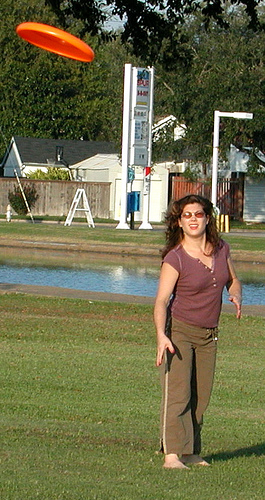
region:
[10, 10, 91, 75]
An orange Frisbee in the air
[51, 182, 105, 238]
A white signboard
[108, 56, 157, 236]
A large white sign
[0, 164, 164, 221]
A brown wooden fence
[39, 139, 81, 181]
A basketball net behind the house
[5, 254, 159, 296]
A stream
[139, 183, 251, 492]
The woman is ready to catch the Frisbee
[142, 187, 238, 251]
She is wearing sunglasses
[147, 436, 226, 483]
The woman is barefoot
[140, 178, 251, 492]
The woman is wearing brown pants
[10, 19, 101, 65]
orange plastic frisbee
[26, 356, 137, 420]
field covered in green grass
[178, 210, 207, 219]
orange tinted eye glasses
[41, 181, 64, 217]
brown wooden privacy fence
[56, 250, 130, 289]
small stream behind field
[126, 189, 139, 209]
blue cover of pay phone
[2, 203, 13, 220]
white fire hydrant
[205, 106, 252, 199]
white metal street light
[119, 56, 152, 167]
large metal company sign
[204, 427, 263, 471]
shadow of woman in field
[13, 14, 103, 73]
frisbee in the air.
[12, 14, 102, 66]
the frisbee is orange.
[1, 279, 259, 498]
the grass is green.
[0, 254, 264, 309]
the water is blue.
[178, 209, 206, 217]
woman is wearing sunglasses.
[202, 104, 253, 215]
the light post is white.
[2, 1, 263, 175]
the trees are green.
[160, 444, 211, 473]
the woman is barefoot.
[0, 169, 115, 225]
the fence is brown.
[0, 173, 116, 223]
the fence is wooden.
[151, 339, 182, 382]
right hand of woman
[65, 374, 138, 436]
green grass behind woman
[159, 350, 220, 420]
grayish green pants of woman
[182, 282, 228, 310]
pink shirt of woman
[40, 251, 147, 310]
body of water behind woman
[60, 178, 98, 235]
pool ladder that is white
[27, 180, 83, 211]
brown fence in background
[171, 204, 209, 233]
orange sunglasses on woman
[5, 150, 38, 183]
white house in distance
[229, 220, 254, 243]
asphalt road in back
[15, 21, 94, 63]
an orange Frisbee thrown in the air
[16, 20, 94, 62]
an orange Frisbee saucer in the air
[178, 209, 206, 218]
sunglasses over the woman's eyes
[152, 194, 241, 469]
woman in brown sweats throwing a Frisbee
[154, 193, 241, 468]
woman in purple t-shirt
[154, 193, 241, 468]
a woman playing Frisbee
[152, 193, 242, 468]
lady playing Frisbee bare feet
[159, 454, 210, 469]
bare feet on the grass in a neighborhood park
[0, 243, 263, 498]
residential park with a small stream of water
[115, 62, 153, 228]
white commercial sign on the other side of the stream of water